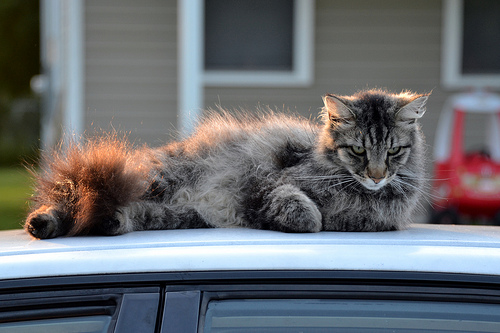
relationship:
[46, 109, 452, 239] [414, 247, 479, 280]
cat on car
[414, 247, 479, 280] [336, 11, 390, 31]
car in front of house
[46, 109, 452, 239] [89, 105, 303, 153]
cat has long fur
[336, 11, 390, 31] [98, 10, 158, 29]
house has tan siding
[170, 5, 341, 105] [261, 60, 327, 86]
window has white frame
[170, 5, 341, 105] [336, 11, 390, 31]
window in house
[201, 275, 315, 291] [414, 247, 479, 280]
window seal on car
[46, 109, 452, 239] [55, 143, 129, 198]
cat has tail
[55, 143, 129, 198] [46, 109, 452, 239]
tail of cat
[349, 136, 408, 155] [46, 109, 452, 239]
eyes of cat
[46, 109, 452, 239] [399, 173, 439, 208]
cat with long whiskers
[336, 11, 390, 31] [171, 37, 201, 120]
house has white trim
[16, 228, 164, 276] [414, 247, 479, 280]
roof of car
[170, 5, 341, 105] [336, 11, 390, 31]
window of house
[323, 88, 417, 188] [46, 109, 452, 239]
head of cat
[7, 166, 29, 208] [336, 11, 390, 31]
lawn by house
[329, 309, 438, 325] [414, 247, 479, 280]
window of car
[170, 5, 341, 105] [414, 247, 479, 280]
window of car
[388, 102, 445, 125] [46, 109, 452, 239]
ear of cat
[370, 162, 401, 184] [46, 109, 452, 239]
nose of cat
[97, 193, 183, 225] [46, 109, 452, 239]
leg of cat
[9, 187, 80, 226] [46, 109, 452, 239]
leg of cat